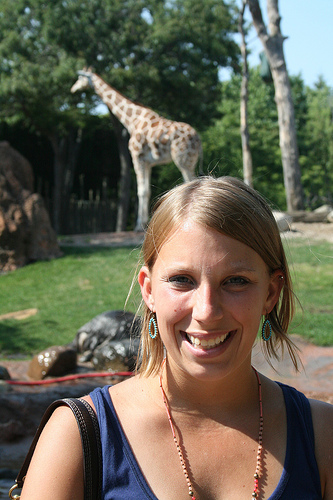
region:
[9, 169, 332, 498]
woman at a zoo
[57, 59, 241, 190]
giraffe at a zoo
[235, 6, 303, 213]
tree trunks in the background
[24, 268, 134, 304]
green grass at a zoo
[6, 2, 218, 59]
green leaves on a tree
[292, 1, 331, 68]
blue sky in the distance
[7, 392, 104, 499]
brown strap of purse on shoulder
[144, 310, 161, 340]
blue earrings on a woman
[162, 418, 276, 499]
necklace on a woman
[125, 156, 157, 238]
front legs of a giraffe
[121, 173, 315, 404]
woman with blonde hair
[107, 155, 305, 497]
woman wearing a necklace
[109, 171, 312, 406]
woman wearing ear rings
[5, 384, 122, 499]
black strap over shoulder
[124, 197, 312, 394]
a woman smiling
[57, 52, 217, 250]
a giraffe stands behind a woman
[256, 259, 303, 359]
a woman's pierced ear and ear ring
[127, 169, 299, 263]
the part in a blonde woman's hair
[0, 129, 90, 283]
a large stone in a giraffe enclosure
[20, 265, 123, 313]
green grass in a giraffe enclosure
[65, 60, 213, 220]
A tall giraffe in the background.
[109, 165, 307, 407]
A woman with blonde hair.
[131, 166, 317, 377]
A woman with a pair of green earrings.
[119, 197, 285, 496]
Necklace around woman's neck.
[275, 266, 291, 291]
A small earring in left ear.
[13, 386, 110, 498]
A black strap across right shoulder.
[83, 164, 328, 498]
Woman in a blue tank top.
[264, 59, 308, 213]
Tall tree trunk on the right.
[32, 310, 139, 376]
A group of large rocks.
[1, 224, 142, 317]
The grass is green.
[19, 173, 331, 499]
a grinning blond woman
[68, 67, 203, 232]
a blurry giraffe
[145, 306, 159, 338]
a dangly blue earring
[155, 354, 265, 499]
a pink beaded necklace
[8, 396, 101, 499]
the strap of a black leather purse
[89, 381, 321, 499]
a dark blue tank top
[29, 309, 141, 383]
big wet rocks behind the woman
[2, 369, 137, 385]
a red hose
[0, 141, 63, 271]
a large rock near the giraffe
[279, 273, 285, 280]
a silver stud earring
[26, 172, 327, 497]
Woman with a blue shirt on.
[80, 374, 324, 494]
Blue shirt on the woman.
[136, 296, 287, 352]
The woman is wearing earrings.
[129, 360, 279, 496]
A pink necklace on the girl.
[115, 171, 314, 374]
The woman is blond.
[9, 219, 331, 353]
The grass is green.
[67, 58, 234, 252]
A giraffe behind the woman.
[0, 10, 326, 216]
The trees are green.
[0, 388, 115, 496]
Black bag strap on the woman's shoulder.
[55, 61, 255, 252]
The giraffe is a statue.